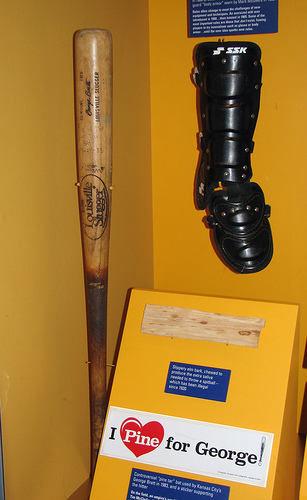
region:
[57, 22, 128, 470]
wooden baseball bat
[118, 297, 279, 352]
small piece of pine tree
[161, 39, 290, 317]
catchers safety knee brace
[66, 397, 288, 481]
bumper sticker with the letter i on it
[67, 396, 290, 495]
bumper sticker with the letter p on it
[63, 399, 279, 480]
bumper sticker with the letter n on it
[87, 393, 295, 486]
bumper sticker with the letter e on it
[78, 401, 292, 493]
bumper sticker with the letter f on it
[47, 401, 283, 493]
bumper sticker with the letter o on it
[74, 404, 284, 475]
bumper sticker with the letter g on it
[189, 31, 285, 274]
black shin guard for baseball catcher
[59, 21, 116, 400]
Old Louisville Slugger baseball bat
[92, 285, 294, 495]
display explaining the what the objects on the wall are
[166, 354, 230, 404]
blue sign with white lettering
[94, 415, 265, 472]
an advertisement with a white background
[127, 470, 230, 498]
blue sign with white lettering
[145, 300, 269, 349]
a wood specimen for the Louisville Slugger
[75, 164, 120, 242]
Louisville Slugger printed on an old bat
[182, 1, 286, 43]
blue sign with white lettering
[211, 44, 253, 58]
white lettering for company SSK, maker of the shin guard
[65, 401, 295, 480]
bumper sticker with the letter r on it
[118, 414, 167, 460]
the heart is red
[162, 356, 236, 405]
the label is blue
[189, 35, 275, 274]
the padding is on the wall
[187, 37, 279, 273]
the padding is black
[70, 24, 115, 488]
the bat is leaning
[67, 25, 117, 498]
the bat is wooden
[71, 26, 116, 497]
the bat is dirty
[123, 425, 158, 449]
the heart says Pine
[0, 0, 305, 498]
the wall is bright yellow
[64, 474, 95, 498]
the wall has brown trim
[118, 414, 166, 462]
Heart shape on bumper sticker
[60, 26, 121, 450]
Baseball bat on display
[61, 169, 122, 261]
Louisville Slugger mark on baseball bat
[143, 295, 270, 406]
Plank of wood on display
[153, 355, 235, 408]
Blue and white sign on display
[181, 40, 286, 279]
Black catcher's shin guard hanging on wall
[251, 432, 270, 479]
Baseball printed in place of exclamation mark on sticker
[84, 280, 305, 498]
Yellow ramp shaped display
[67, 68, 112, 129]
Autograph on baseball bat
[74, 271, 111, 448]
Pine tar residue on baseball bat